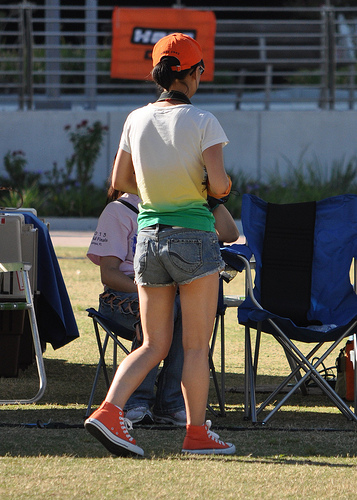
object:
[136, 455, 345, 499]
grass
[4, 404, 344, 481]
ground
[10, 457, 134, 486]
grass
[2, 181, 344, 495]
ground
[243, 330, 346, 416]
base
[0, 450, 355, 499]
ground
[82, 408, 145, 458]
foot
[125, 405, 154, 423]
sneaker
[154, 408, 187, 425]
sneaker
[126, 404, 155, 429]
foot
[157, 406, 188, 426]
foot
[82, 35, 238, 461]
girl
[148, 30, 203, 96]
head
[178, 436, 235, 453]
foot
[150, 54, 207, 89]
hair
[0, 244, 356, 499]
grass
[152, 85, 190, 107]
neck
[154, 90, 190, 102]
strap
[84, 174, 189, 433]
woman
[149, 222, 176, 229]
belt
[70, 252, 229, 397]
black lawn chair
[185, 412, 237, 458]
right orange sneaker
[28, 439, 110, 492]
grass on the ground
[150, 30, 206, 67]
baseball cap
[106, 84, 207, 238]
brush along the back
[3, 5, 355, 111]
metal fence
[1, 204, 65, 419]
chair folded up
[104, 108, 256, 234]
green t shirt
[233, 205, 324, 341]
black chair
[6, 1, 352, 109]
thin grey fence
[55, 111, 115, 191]
green rose bush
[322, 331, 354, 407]
dark brown cart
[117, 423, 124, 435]
orange and white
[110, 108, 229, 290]
back of a girl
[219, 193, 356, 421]
blue chair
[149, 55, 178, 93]
black pony tail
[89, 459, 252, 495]
behind the girl's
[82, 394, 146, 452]
orange shoe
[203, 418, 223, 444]
white shoelaces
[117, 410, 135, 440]
white shoelaces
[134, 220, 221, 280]
blue denim shorts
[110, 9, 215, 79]
orange banner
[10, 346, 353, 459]
shaded area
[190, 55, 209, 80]
pair of glasses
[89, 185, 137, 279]
pink tee shirt